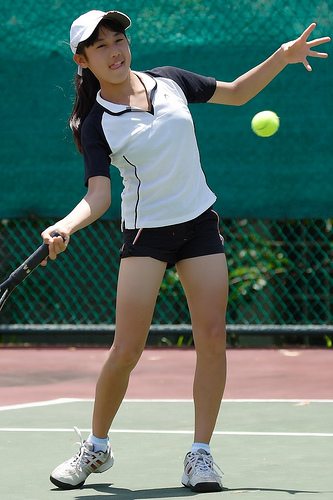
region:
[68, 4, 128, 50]
Person wearing white hat.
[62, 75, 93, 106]
Person has long hair.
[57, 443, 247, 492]
Person wearing white shoes.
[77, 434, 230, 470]
Person wearing white socks.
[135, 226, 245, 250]
Person wearing black shorts.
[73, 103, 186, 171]
Person wearing black and white shirt.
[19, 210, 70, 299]
Grip on racket is black.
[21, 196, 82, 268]
Person swinging black tennis racket.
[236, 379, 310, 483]
White lines marking tennis court.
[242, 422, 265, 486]
Tennis court is green.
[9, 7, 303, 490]
a little girl playing tennis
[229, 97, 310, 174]
tennis ball in the air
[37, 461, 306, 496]
girl`s shadow on the ground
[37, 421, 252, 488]
girl is wearing white sneakers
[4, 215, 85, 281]
girl is holding the tennis racket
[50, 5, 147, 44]
the hat is white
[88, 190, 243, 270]
the girl is wearing shorts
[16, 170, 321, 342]
the fence is green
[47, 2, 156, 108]
the girl is asian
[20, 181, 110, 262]
the sun is on the girl`s arm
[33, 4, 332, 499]
Young girl playing tennis on tennis court.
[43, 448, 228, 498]
Girl wearing white tennis shoes with red accents.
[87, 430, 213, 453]
Girl wearing ankle high white socks.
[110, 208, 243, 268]
Young girl dressed in black short shorts with red and white accents.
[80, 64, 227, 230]
Young girl dressed in white and black shirt.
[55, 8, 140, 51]
Young girl wearing white cap on head.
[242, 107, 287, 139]
Yellow tennis ball in air.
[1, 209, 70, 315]
Handle of tennis racket in girl's hand.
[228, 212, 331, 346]
Green fence running behind tennis court.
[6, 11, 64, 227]
Green net over top part of green fence.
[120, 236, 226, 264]
her short is too short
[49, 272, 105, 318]
the chainlink fence is blue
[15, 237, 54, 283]
the handle is black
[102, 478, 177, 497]
shadow is on the ground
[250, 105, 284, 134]
the ball is in the air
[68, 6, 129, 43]
the cap is white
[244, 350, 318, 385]
the ground is brown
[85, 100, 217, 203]
the shirt is black and white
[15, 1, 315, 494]
the girl is caucassesn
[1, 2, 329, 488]
the game played is tennis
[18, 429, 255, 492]
Athletic shoes for tennis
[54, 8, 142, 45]
Baseball cap to block sun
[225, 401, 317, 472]
Green tennis court with white lines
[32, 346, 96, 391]
Red section of flooring around court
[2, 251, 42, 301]
Handle part of tennis racquet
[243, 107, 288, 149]
Flourescent yellow tennis ball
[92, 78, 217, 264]
Tennis apparel shorts and shirt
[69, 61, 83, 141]
Long black ponytail hair style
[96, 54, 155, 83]
Tongue sticking out in concentration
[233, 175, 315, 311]
Chain link fence around court